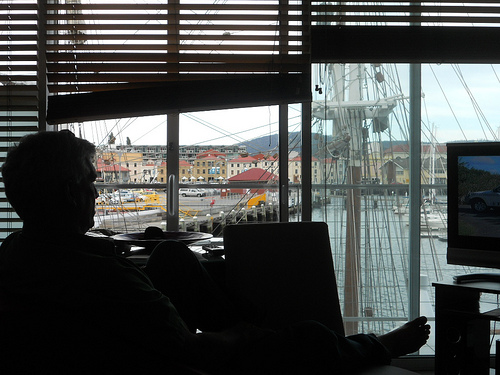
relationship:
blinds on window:
[48, 23, 499, 125] [1, 0, 498, 375]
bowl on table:
[111, 225, 216, 247] [36, 222, 252, 262]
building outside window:
[92, 143, 451, 228] [1, 0, 306, 237]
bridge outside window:
[176, 200, 282, 225] [41, 1, 311, 223]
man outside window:
[0, 127, 432, 374] [1, 0, 498, 375]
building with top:
[223, 164, 284, 198] [228, 162, 285, 182]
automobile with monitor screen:
[462, 186, 497, 217] [458, 154, 499, 234]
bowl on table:
[111, 225, 213, 249] [122, 233, 227, 267]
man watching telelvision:
[0, 127, 432, 374] [442, 138, 497, 268]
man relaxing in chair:
[13, 135, 437, 351] [10, 263, 145, 373]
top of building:
[229, 166, 280, 182] [212, 145, 302, 202]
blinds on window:
[0, 0, 499, 245] [1, 1, 39, 250]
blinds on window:
[0, 0, 499, 245] [54, 1, 309, 236]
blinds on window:
[0, 0, 499, 245] [310, 2, 498, 355]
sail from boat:
[297, 55, 451, 350] [296, 75, 417, 357]